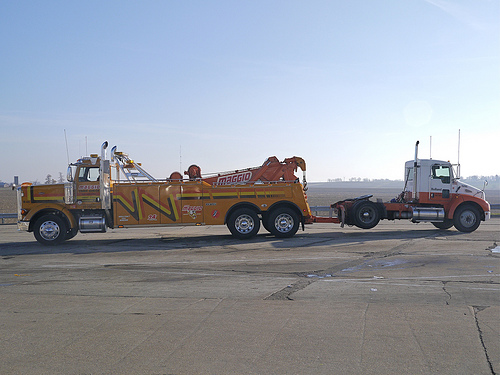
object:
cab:
[328, 128, 491, 234]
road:
[0, 216, 500, 374]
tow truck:
[14, 127, 316, 247]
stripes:
[113, 182, 139, 225]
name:
[215, 170, 253, 186]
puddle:
[336, 250, 411, 274]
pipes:
[99, 140, 114, 229]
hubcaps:
[32, 213, 67, 247]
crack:
[267, 257, 337, 283]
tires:
[226, 206, 261, 240]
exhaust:
[413, 139, 420, 165]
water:
[338, 250, 410, 263]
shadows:
[0, 229, 462, 261]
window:
[430, 163, 450, 184]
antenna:
[455, 128, 461, 179]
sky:
[0, 0, 500, 185]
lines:
[175, 190, 285, 198]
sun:
[388, 72, 494, 156]